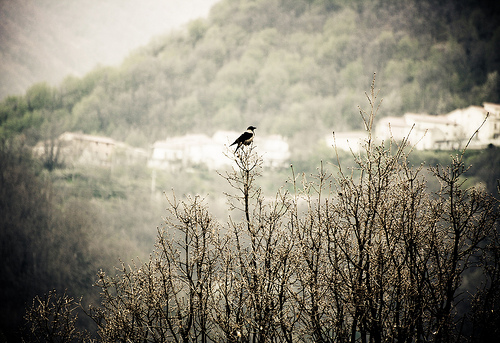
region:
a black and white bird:
[230, 116, 257, 156]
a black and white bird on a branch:
[221, 116, 264, 184]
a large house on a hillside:
[37, 122, 143, 170]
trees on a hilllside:
[209, 6, 426, 102]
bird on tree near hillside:
[66, 71, 473, 224]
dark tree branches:
[337, 142, 464, 323]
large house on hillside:
[331, 116, 499, 146]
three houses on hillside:
[22, 106, 497, 151]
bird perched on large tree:
[228, 114, 292, 341]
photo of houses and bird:
[36, 16, 453, 303]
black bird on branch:
[227, 117, 266, 150]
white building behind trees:
[383, 98, 496, 138]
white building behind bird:
[169, 123, 284, 183]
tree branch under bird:
[226, 155, 299, 272]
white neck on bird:
[244, 130, 256, 139]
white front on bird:
[251, 127, 257, 138]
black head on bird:
[247, 123, 259, 134]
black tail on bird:
[231, 132, 242, 149]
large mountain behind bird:
[148, 15, 450, 142]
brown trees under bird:
[150, 190, 488, 331]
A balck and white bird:
[231, 122, 256, 153]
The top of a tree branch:
[360, 67, 384, 112]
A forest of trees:
[116, 57, 268, 104]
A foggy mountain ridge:
[24, 25, 196, 121]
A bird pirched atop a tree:
[129, 98, 394, 310]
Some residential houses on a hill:
[32, 127, 220, 170]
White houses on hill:
[350, 117, 497, 145]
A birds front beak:
[251, 124, 256, 129]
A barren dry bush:
[102, 258, 440, 331]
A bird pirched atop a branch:
[220, 118, 269, 211]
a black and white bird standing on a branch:
[228, 122, 260, 153]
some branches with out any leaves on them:
[207, 202, 401, 313]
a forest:
[185, 31, 332, 108]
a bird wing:
[232, 131, 249, 146]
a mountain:
[31, 0, 118, 68]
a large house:
[45, 133, 122, 167]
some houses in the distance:
[375, 100, 497, 152]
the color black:
[237, 131, 249, 144]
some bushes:
[15, 202, 72, 265]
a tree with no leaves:
[40, 106, 70, 180]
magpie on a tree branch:
[225, 121, 260, 151]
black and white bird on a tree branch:
[228, 124, 258, 151]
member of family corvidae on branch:
[228, 125, 258, 155]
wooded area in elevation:
[63, 9, 393, 124]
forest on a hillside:
[35, 11, 334, 124]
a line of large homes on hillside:
[48, 94, 492, 177]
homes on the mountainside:
[31, 102, 495, 196]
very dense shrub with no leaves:
[160, 190, 237, 337]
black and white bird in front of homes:
[150, 87, 332, 233]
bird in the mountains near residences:
[10, 3, 473, 309]